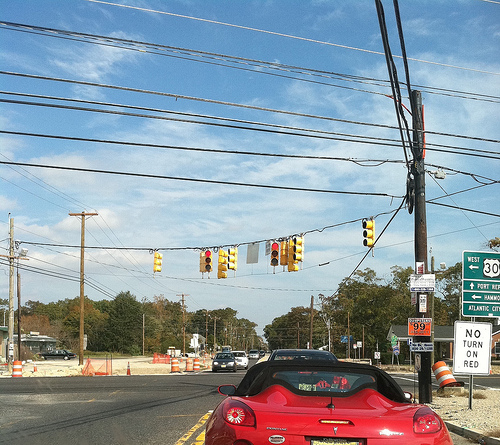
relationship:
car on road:
[200, 358, 455, 443] [22, 377, 197, 439]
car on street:
[200, 358, 455, 443] [46, 386, 158, 436]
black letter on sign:
[465, 329, 472, 336] [451, 319, 493, 376]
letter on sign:
[458, 321, 472, 341] [455, 321, 489, 373]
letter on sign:
[469, 337, 478, 349] [451, 319, 493, 376]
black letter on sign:
[465, 329, 472, 336] [442, 315, 497, 382]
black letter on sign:
[464, 360, 468, 367] [445, 300, 494, 363]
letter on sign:
[469, 347, 480, 359] [449, 314, 496, 408]